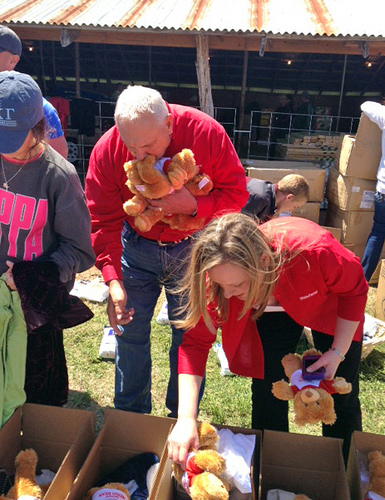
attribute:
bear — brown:
[275, 349, 351, 426]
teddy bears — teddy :
[49, 429, 271, 495]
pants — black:
[246, 307, 360, 434]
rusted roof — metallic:
[0, 0, 383, 39]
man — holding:
[78, 83, 232, 417]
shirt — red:
[176, 216, 369, 378]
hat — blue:
[1, 69, 49, 154]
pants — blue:
[114, 219, 204, 417]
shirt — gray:
[4, 160, 90, 268]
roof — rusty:
[0, 3, 376, 40]